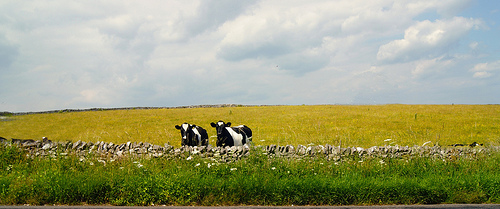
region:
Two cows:
[166, 112, 264, 154]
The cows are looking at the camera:
[157, 108, 267, 143]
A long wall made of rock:
[18, 136, 487, 173]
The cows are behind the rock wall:
[0, 99, 489, 160]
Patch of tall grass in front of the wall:
[9, 148, 491, 205]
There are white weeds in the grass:
[27, 140, 464, 175]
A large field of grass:
[22, 99, 494, 144]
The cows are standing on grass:
[153, 120, 267, 145]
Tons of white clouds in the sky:
[7, 11, 481, 93]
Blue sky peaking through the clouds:
[461, 9, 495, 54]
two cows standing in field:
[172, 120, 253, 145]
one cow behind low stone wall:
[172, 119, 209, 162]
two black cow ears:
[208, 119, 231, 129]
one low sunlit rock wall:
[13, 139, 496, 161]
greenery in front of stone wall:
[44, 144, 485, 198]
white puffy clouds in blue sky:
[87, 11, 450, 86]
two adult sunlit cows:
[165, 107, 255, 152]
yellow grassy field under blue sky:
[278, 74, 380, 119]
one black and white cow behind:
[238, 120, 253, 140]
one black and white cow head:
[178, 122, 193, 142]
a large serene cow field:
[4, 6, 476, 207]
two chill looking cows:
[158, 111, 255, 150]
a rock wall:
[20, 127, 499, 163]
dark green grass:
[21, 164, 448, 204]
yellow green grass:
[253, 109, 476, 133]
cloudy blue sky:
[15, 5, 497, 92]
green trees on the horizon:
[6, 88, 255, 119]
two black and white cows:
[171, 117, 300, 159]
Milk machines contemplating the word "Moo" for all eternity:
[173, 101, 272, 152]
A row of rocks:
[32, 136, 471, 177]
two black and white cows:
[175, 121, 250, 146]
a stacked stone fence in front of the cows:
[5, 143, 497, 154]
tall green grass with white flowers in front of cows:
[13, 155, 489, 207]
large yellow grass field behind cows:
[16, 103, 496, 140]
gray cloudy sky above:
[2, 3, 499, 101]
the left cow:
[176, 122, 206, 147]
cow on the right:
[212, 120, 249, 147]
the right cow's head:
[210, 119, 230, 137]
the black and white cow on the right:
[210, 119, 251, 144]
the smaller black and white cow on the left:
[175, 123, 207, 146]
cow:
[160, 121, 202, 156]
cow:
[197, 108, 244, 150]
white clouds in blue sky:
[12, 8, 52, 35]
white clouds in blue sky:
[405, 56, 446, 83]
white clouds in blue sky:
[411, 11, 438, 43]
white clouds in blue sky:
[334, 16, 391, 50]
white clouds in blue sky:
[288, 13, 340, 55]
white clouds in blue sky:
[187, 31, 251, 69]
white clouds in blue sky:
[82, 5, 137, 57]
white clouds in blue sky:
[152, 16, 196, 60]